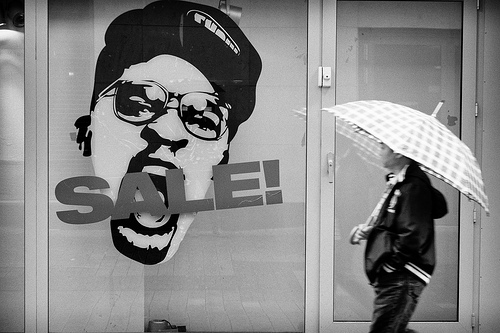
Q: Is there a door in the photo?
A: Yes, there is a door.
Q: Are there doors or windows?
A: Yes, there is a door.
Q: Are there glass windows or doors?
A: Yes, there is a glass door.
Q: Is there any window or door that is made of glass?
A: Yes, the door is made of glass.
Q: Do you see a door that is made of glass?
A: Yes, there is a door that is made of glass.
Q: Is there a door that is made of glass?
A: Yes, there is a door that is made of glass.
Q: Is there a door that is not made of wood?
A: Yes, there is a door that is made of glass.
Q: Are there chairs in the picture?
A: No, there are no chairs.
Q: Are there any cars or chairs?
A: No, there are no chairs or cars.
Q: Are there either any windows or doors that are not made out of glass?
A: No, there is a door but it is made of glass.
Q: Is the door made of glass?
A: Yes, the door is made of glass.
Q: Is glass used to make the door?
A: Yes, the door is made of glass.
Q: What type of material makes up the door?
A: The door is made of glass.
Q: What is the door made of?
A: The door is made of glass.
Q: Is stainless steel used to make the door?
A: No, the door is made of glass.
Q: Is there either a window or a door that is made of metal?
A: No, there is a door but it is made of glass.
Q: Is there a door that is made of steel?
A: No, there is a door but it is made of glass.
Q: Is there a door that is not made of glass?
A: No, there is a door but it is made of glass.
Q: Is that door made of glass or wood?
A: The door is made of glass.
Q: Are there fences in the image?
A: No, there are no fences.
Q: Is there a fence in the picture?
A: No, there are no fences.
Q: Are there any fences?
A: No, there are no fences.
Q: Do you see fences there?
A: No, there are no fences.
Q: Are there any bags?
A: No, there are no bags.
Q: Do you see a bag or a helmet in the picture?
A: No, there are no bags or helmets.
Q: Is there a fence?
A: No, there are no fences.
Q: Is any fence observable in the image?
A: No, there are no fences.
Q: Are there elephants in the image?
A: No, there are no elephants.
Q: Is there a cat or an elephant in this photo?
A: No, there are no elephants or cats.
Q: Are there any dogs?
A: No, there are no dogs.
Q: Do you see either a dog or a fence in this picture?
A: No, there are no dogs or fences.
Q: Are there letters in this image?
A: Yes, there are letters.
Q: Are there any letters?
A: Yes, there are letters.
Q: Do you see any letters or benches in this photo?
A: Yes, there are letters.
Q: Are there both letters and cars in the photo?
A: No, there are letters but no cars.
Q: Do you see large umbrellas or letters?
A: Yes, there are large letters.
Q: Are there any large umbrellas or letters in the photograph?
A: Yes, there are large letters.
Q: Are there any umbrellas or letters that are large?
A: Yes, the letters are large.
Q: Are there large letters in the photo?
A: Yes, there are large letters.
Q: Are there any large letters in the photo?
A: Yes, there are large letters.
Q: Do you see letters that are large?
A: Yes, there are letters that are large.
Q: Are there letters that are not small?
A: Yes, there are large letters.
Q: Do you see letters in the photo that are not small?
A: Yes, there are large letters.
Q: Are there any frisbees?
A: No, there are no frisbees.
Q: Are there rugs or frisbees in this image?
A: No, there are no frisbees or rugs.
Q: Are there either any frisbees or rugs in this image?
A: No, there are no frisbees or rugs.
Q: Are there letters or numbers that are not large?
A: No, there are letters but they are large.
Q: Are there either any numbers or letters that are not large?
A: No, there are letters but they are large.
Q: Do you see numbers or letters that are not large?
A: No, there are letters but they are large.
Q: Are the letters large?
A: Yes, the letters are large.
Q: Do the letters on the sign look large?
A: Yes, the letters are large.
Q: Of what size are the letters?
A: The letters are large.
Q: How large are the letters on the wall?
A: The letters are large.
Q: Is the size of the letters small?
A: No, the letters are large.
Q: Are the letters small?
A: No, the letters are large.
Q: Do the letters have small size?
A: No, the letters are large.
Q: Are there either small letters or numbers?
A: No, there are letters but they are large.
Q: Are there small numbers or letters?
A: No, there are letters but they are large.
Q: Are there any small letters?
A: No, there are letters but they are large.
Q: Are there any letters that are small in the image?
A: No, there are letters but they are large.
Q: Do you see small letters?
A: No, there are letters but they are large.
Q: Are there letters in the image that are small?
A: No, there are letters but they are large.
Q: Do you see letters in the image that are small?
A: No, there are letters but they are large.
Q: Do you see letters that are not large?
A: No, there are letters but they are large.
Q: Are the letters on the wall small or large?
A: The letters are large.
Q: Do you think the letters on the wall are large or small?
A: The letters are large.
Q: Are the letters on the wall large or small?
A: The letters are large.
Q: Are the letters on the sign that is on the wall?
A: Yes, the letters are on the sign.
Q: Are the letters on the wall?
A: Yes, the letters are on the wall.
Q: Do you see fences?
A: No, there are no fences.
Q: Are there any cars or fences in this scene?
A: No, there are no fences or cars.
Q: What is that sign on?
A: The sign is on the wall.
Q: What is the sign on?
A: The sign is on the wall.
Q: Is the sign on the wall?
A: Yes, the sign is on the wall.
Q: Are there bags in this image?
A: No, there are no bags.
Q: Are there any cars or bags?
A: No, there are no bags or cars.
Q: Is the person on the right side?
A: Yes, the person is on the right of the image.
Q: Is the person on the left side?
A: No, the person is on the right of the image.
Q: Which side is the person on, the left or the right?
A: The person is on the right of the image.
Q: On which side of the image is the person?
A: The person is on the right of the image.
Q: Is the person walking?
A: Yes, the person is walking.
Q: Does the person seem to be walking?
A: Yes, the person is walking.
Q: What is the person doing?
A: The person is walking.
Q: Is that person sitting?
A: No, the person is walking.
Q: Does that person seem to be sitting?
A: No, the person is walking.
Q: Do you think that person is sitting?
A: No, the person is walking.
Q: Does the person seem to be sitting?
A: No, the person is walking.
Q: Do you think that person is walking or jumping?
A: The person is walking.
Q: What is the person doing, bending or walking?
A: The person is walking.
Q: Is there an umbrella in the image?
A: Yes, there is an umbrella.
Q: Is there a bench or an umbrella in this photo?
A: Yes, there is an umbrella.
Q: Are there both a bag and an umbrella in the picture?
A: No, there is an umbrella but no bags.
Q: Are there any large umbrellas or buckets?
A: Yes, there is a large umbrella.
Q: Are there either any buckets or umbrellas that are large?
A: Yes, the umbrella is large.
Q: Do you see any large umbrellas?
A: Yes, there is a large umbrella.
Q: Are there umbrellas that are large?
A: Yes, there is an umbrella that is large.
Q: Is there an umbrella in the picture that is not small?
A: Yes, there is a large umbrella.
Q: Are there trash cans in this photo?
A: No, there are no trash cans.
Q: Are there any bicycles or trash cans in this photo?
A: No, there are no trash cans or bicycles.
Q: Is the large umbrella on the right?
A: Yes, the umbrella is on the right of the image.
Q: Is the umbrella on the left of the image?
A: No, the umbrella is on the right of the image.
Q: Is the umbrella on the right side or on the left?
A: The umbrella is on the right of the image.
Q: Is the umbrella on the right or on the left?
A: The umbrella is on the right of the image.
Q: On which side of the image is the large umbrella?
A: The umbrella is on the right of the image.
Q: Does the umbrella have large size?
A: Yes, the umbrella is large.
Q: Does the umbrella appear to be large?
A: Yes, the umbrella is large.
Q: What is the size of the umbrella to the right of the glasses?
A: The umbrella is large.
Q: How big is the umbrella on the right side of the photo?
A: The umbrella is large.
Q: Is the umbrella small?
A: No, the umbrella is large.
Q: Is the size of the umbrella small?
A: No, the umbrella is large.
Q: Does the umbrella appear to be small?
A: No, the umbrella is large.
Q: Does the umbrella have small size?
A: No, the umbrella is large.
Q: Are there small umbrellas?
A: No, there is an umbrella but it is large.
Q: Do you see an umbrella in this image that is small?
A: No, there is an umbrella but it is large.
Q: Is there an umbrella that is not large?
A: No, there is an umbrella but it is large.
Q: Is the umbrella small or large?
A: The umbrella is large.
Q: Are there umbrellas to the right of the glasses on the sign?
A: Yes, there is an umbrella to the right of the glasses.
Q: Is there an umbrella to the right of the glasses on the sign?
A: Yes, there is an umbrella to the right of the glasses.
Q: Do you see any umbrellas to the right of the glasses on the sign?
A: Yes, there is an umbrella to the right of the glasses.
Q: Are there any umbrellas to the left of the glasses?
A: No, the umbrella is to the right of the glasses.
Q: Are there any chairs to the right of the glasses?
A: No, there is an umbrella to the right of the glasses.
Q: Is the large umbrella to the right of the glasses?
A: Yes, the umbrella is to the right of the glasses.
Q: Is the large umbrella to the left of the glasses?
A: No, the umbrella is to the right of the glasses.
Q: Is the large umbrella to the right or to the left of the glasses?
A: The umbrella is to the right of the glasses.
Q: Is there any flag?
A: No, there are no flags.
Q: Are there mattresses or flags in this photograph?
A: No, there are no flags or mattresses.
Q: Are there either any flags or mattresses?
A: No, there are no flags or mattresses.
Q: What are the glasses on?
A: The glasses are on the sign.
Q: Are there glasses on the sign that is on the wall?
A: Yes, there are glasses on the sign.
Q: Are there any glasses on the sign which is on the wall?
A: Yes, there are glasses on the sign.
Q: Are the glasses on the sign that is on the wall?
A: Yes, the glasses are on the sign.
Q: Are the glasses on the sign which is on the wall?
A: Yes, the glasses are on the sign.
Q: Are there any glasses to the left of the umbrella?
A: Yes, there are glasses to the left of the umbrella.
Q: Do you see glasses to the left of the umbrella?
A: Yes, there are glasses to the left of the umbrella.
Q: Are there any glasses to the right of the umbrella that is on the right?
A: No, the glasses are to the left of the umbrella.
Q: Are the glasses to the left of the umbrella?
A: Yes, the glasses are to the left of the umbrella.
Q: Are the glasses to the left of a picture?
A: No, the glasses are to the left of the umbrella.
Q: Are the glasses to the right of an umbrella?
A: No, the glasses are to the left of an umbrella.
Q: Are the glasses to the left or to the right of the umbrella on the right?
A: The glasses are to the left of the umbrella.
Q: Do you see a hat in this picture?
A: Yes, there is a hat.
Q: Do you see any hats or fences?
A: Yes, there is a hat.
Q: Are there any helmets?
A: No, there are no helmets.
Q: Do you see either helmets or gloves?
A: No, there are no helmets or gloves.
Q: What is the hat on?
A: The hat is on the sign.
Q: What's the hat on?
A: The hat is on the sign.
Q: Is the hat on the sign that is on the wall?
A: Yes, the hat is on the sign.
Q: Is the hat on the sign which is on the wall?
A: Yes, the hat is on the sign.